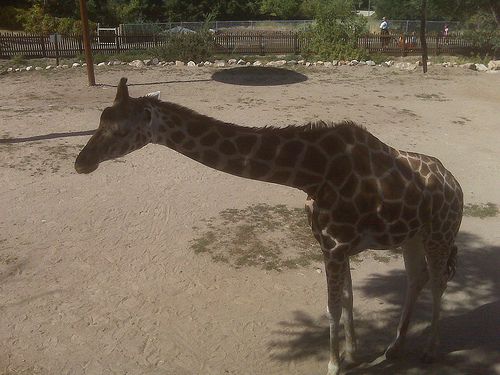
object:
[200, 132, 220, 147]
spot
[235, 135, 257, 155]
spot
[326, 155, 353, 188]
spot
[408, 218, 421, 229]
spot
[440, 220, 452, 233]
spot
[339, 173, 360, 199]
spot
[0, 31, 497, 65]
brown fence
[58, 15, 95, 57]
trees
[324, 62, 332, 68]
rock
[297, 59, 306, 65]
rock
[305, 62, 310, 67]
rock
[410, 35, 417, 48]
children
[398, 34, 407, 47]
children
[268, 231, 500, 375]
shadow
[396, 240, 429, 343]
leg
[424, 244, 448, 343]
leg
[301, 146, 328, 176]
spot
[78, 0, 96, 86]
brown pole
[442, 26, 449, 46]
children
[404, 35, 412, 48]
children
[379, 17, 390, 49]
mother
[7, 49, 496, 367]
sand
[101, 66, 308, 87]
shadow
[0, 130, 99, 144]
shadow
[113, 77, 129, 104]
ear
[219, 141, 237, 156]
spot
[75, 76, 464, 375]
giraffe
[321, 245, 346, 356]
leg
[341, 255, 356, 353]
leg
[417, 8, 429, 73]
tree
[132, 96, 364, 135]
hair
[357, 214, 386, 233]
spot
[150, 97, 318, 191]
neck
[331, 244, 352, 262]
spot giraffe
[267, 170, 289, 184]
spot giraffe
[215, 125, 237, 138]
spot giraffe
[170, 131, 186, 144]
spot giraffe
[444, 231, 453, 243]
spot giraffe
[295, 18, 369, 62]
bush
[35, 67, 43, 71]
stones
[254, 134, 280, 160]
spot giraffe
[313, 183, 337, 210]
spot giraffe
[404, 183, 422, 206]
spot giraffe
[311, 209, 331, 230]
spot giraffe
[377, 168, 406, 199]
spot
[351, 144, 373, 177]
spot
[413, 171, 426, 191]
spot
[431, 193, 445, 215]
spot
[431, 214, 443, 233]
spot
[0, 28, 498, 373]
zoo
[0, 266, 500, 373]
dirt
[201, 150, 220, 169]
spots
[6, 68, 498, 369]
ground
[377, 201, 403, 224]
spot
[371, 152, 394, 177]
spot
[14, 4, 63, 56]
tree